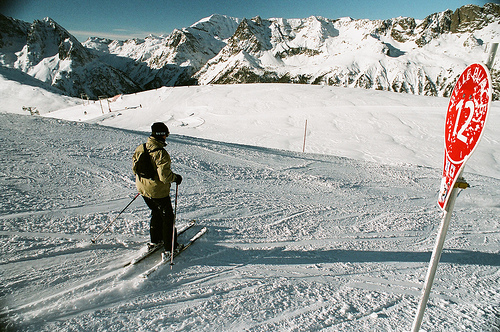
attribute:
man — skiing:
[128, 117, 185, 265]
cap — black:
[149, 120, 171, 139]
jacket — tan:
[131, 139, 179, 202]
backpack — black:
[134, 142, 166, 184]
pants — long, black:
[136, 195, 184, 259]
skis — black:
[132, 217, 210, 282]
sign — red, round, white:
[437, 63, 494, 214]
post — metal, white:
[408, 39, 499, 331]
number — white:
[450, 98, 476, 148]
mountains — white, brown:
[1, 5, 499, 96]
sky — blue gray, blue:
[1, 2, 496, 17]